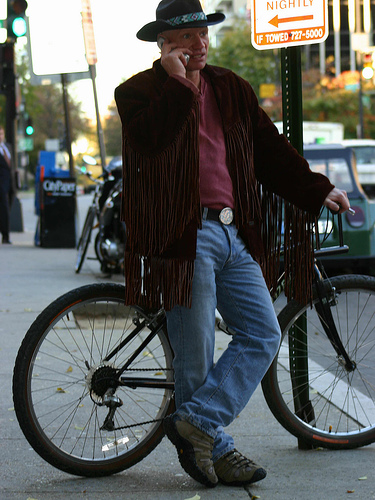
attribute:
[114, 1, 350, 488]
man — dressed western, older, leaning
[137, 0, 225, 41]
hat — black, round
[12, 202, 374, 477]
bicycle — black, here, small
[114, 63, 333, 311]
coat — unique, brown, fringed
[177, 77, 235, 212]
shirt — red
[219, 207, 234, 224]
belt buckle — large, round, silver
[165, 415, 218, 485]
shoe — brown, here, black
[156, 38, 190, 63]
phone — silver, gray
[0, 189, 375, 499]
sidewalk — here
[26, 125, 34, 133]
light — green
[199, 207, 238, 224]
belt — black